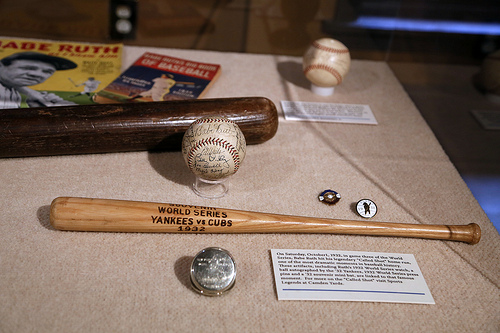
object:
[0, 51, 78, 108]
babe ruth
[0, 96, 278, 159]
baseball bat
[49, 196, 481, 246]
baseball bat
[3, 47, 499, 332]
table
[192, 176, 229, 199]
stand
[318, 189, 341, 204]
baseball pin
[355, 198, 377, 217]
baseball pin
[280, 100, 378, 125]
information card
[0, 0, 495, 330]
display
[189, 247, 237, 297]
coin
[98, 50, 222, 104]
book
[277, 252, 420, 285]
writing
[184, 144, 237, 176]
writing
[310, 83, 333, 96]
base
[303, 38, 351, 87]
ball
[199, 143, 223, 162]
autographs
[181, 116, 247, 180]
ball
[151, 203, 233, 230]
words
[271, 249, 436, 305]
card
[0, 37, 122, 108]
book